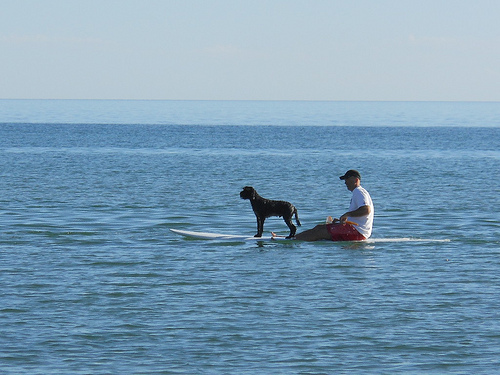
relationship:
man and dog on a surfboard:
[317, 147, 396, 265] [172, 215, 210, 283]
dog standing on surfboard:
[237, 183, 302, 239] [167, 225, 453, 246]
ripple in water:
[51, 229, 103, 237] [3, 123, 495, 371]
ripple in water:
[105, 269, 163, 280] [3, 123, 495, 371]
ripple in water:
[367, 299, 450, 308] [3, 123, 495, 371]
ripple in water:
[201, 330, 244, 338] [3, 123, 495, 371]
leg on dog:
[252, 212, 277, 246] [237, 183, 304, 241]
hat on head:
[343, 169, 363, 181] [338, 169, 365, 191]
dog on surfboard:
[237, 183, 304, 241] [167, 222, 452, 251]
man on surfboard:
[281, 169, 374, 241] [167, 222, 452, 251]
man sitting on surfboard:
[281, 169, 374, 241] [165, 225, 454, 252]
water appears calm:
[3, 123, 495, 371] [35, 270, 429, 368]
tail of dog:
[292, 217, 304, 227] [240, 185, 304, 239]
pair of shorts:
[309, 217, 365, 245] [332, 224, 351, 245]